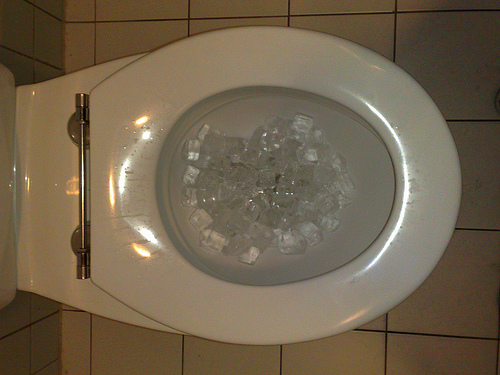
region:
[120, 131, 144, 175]
spilt water on a toilet seat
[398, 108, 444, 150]
A seat of a toilet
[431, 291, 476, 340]
tiles on the floor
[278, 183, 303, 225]
ice in the toilet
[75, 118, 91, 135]
hinge to a toilet seat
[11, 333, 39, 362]
tiles on the wall of a toilet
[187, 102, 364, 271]
the inside of a toilet sink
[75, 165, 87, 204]
a metal bar holding the toilet seat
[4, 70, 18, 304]
the part of the the toilet sink attached to the wall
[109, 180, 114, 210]
reflection of light from the lit bulb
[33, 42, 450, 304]
the seat is wet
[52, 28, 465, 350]
the seat is white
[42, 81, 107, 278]
the fixture is silver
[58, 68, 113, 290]
the fixture is metal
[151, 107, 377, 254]
ice in the toilet bowl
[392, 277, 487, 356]
the floor is off white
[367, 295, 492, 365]
the floor is tiled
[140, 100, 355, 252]
the ice is in cubes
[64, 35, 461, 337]
the seat is down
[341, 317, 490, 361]
lines are in the floor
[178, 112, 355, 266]
some ice in a toilet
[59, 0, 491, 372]
a white tiled floor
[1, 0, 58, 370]
a white tiled wall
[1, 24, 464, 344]
A large white toilet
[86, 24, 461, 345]
A white toilet seat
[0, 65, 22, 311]
a water basin on a toilet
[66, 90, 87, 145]
A silver colored metal hinge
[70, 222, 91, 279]
A silver colored metal hinge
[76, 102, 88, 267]
A metal bar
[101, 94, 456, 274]
some liquid on the toilet seat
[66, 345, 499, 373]
beige bathroom floor tile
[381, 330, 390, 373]
chocolate brown tile grout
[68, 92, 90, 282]
metal toilet seat hinge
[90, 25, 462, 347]
a white toilet seat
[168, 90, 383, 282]
the water in the toilet bowl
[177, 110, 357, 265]
ice cubes in the toilet bowl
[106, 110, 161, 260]
a light glare on the toilet seat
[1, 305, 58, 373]
beige tiled bathroom wall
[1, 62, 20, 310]
the water holding tank against the wall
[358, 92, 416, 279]
a reflection of light on the toilet seat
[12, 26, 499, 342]
ice cubes in this toilet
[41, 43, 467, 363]
this toilet seat is white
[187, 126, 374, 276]
the ice looks fresh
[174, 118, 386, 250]
no water in the toilet bowl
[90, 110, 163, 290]
water on the lid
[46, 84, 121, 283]
a hinge on the toilet seat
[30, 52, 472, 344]
this toilet seat is clean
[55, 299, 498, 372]
a tan floor beneath the seat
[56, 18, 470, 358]
this toilet is not being used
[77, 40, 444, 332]
the ice is makig the toilet bowl cold